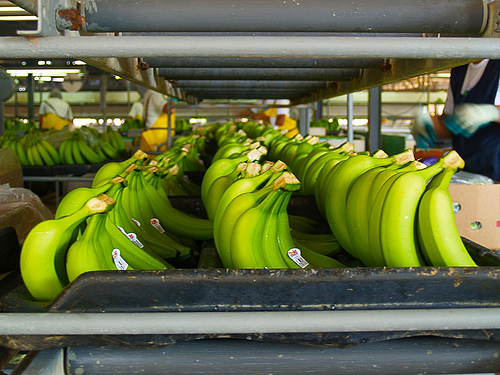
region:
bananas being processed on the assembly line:
[3, 119, 480, 297]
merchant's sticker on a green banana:
[286, 247, 308, 269]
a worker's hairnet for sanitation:
[46, 87, 64, 101]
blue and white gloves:
[407, 104, 497, 154]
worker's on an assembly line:
[36, 88, 177, 154]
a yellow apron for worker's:
[140, 104, 174, 156]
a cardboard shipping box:
[427, 169, 498, 256]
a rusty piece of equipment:
[52, 4, 87, 36]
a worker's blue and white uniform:
[422, 60, 498, 189]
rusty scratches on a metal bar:
[87, 264, 499, 284]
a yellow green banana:
[379, 162, 444, 267]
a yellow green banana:
[415, 166, 475, 269]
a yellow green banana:
[231, 189, 277, 266]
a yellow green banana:
[263, 184, 290, 269]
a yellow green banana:
[279, 184, 310, 268]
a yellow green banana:
[215, 158, 278, 249]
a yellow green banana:
[67, 212, 97, 277]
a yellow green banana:
[19, 205, 87, 300]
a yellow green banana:
[103, 219, 165, 270]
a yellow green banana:
[54, 177, 109, 219]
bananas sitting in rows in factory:
[4, 110, 481, 302]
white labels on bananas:
[108, 213, 165, 272]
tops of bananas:
[226, 118, 302, 193]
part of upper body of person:
[408, 54, 499, 181]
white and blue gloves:
[410, 103, 497, 147]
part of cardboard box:
[443, 171, 499, 259]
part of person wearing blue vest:
[407, 55, 499, 186]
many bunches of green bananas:
[1, 112, 479, 303]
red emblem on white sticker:
[288, 246, 298, 256]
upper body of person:
[31, 87, 76, 134]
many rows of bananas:
[8, 108, 470, 273]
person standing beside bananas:
[413, 63, 498, 158]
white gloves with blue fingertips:
[409, 100, 490, 137]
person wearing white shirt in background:
[33, 81, 75, 136]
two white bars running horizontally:
[0, 26, 499, 330]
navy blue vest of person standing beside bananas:
[442, 63, 498, 171]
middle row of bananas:
[200, 114, 313, 261]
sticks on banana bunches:
[106, 212, 167, 272]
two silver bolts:
[449, 202, 487, 234]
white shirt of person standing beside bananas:
[437, 63, 498, 119]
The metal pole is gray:
[23, 302, 478, 348]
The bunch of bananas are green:
[208, 163, 306, 273]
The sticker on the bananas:
[283, 243, 310, 271]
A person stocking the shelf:
[413, 55, 498, 272]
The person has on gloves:
[404, 98, 495, 154]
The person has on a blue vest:
[448, 61, 499, 182]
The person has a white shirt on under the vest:
[441, 55, 498, 115]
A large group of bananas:
[23, 95, 475, 257]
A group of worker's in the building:
[36, 75, 311, 157]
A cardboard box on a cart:
[433, 151, 499, 256]